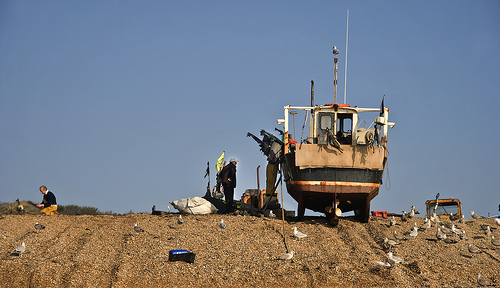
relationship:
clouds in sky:
[26, 15, 473, 165] [0, 0, 499, 217]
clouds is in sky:
[26, 15, 473, 165] [0, 0, 499, 217]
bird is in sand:
[288, 226, 308, 241] [2, 203, 496, 285]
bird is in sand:
[13, 240, 27, 259] [1, 215, 498, 286]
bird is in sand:
[279, 250, 295, 265] [1, 215, 498, 286]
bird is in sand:
[288, 226, 308, 241] [1, 215, 498, 286]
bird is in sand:
[380, 235, 398, 248] [1, 215, 498, 286]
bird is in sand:
[435, 227, 447, 242] [1, 215, 498, 286]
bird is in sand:
[474, 272, 489, 285] [2, 203, 496, 285]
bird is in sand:
[464, 234, 488, 262] [25, 233, 498, 281]